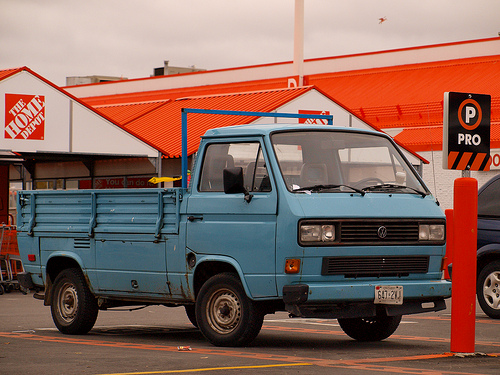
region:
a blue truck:
[3, 66, 483, 372]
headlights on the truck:
[304, 217, 454, 248]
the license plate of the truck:
[368, 280, 413, 312]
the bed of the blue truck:
[3, 169, 208, 266]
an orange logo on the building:
[0, 82, 81, 175]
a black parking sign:
[426, 79, 498, 181]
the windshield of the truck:
[267, 122, 422, 200]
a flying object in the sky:
[360, 8, 411, 23]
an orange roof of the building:
[15, 57, 310, 140]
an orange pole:
[440, 172, 495, 362]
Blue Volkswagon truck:
[0, 92, 480, 352]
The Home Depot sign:
[1, 77, 66, 151]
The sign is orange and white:
[4, 70, 167, 166]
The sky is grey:
[6, 0, 485, 62]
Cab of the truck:
[177, 108, 458, 319]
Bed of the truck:
[6, 170, 223, 320]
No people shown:
[12, 17, 489, 366]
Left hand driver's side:
[294, 140, 409, 217]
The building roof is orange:
[55, 37, 494, 167]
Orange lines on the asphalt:
[9, 288, 466, 373]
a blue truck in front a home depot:
[3, 96, 452, 354]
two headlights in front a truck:
[291, 210, 447, 253]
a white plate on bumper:
[368, 281, 409, 313]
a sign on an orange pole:
[428, 78, 498, 179]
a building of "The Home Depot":
[3, 68, 417, 168]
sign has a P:
[435, 84, 497, 174]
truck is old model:
[5, 78, 452, 358]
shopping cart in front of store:
[3, 213, 26, 298]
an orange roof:
[103, 65, 445, 132]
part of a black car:
[459, 172, 499, 332]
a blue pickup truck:
[10, 102, 449, 352]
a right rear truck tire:
[43, 269, 96, 336]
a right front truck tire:
[190, 269, 262, 351]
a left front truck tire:
[328, 308, 403, 345]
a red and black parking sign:
[438, 86, 493, 357]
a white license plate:
[369, 283, 403, 308]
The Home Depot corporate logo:
[0, 89, 48, 147]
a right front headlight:
[293, 217, 337, 244]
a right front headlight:
[410, 222, 447, 244]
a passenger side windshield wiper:
[293, 173, 365, 198]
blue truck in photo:
[44, 112, 392, 352]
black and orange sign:
[427, 90, 495, 170]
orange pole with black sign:
[424, 87, 485, 364]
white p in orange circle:
[448, 91, 485, 143]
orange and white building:
[10, 47, 462, 157]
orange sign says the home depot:
[10, 78, 77, 163]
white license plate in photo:
[337, 265, 432, 315]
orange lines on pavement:
[12, 282, 429, 372]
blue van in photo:
[432, 138, 497, 315]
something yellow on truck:
[141, 155, 185, 193]